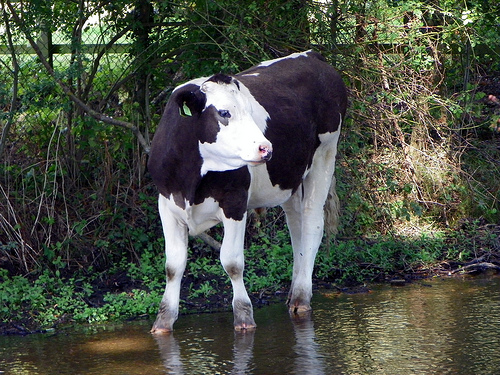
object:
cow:
[142, 42, 350, 337]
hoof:
[227, 301, 257, 329]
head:
[152, 76, 270, 167]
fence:
[1, 20, 152, 147]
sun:
[310, 0, 499, 239]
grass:
[396, 231, 449, 272]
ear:
[168, 81, 207, 116]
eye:
[215, 110, 232, 121]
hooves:
[147, 320, 176, 335]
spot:
[204, 74, 230, 84]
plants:
[0, 263, 62, 335]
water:
[0, 265, 499, 375]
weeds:
[0, 229, 499, 333]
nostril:
[259, 144, 267, 154]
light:
[309, 0, 472, 237]